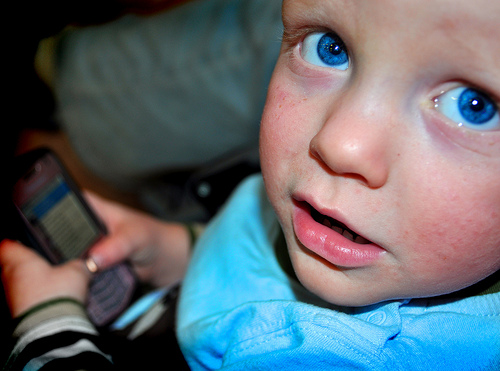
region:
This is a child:
[0, 5, 492, 365]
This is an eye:
[408, 48, 498, 170]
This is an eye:
[280, 23, 361, 89]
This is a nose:
[305, 105, 398, 197]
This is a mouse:
[271, 182, 448, 294]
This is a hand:
[71, 161, 204, 301]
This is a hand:
[10, 233, 90, 350]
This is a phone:
[13, 157, 155, 357]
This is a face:
[252, 0, 499, 335]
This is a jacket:
[188, 203, 478, 360]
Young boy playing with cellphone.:
[2, 0, 499, 370]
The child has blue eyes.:
[291, 20, 498, 169]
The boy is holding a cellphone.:
[21, 135, 145, 308]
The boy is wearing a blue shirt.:
[181, 224, 256, 341]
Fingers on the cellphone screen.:
[86, 245, 124, 287]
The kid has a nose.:
[320, 103, 396, 185]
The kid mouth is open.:
[293, 182, 393, 294]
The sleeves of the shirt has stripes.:
[23, 307, 98, 362]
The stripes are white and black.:
[32, 326, 96, 354]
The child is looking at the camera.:
[255, 38, 497, 293]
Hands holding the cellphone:
[8, 154, 147, 323]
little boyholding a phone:
[7, 3, 497, 361]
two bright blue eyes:
[294, 20, 499, 145]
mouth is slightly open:
[284, 183, 378, 266]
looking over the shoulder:
[182, 12, 497, 366]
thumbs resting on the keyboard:
[62, 239, 119, 281]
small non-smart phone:
[8, 141, 145, 323]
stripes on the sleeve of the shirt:
[14, 299, 110, 369]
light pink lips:
[286, 185, 378, 275]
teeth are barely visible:
[314, 216, 364, 247]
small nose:
[299, 94, 404, 190]